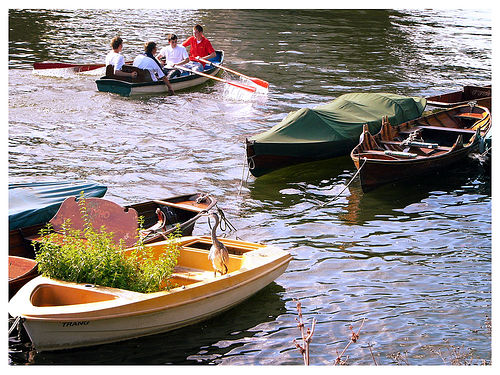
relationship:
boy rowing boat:
[177, 24, 217, 76] [90, 26, 243, 101]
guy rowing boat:
[157, 29, 195, 75] [90, 26, 243, 101]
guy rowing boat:
[131, 41, 177, 96] [90, 26, 243, 101]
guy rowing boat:
[100, 32, 139, 82] [90, 26, 243, 101]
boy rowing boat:
[177, 24, 217, 76] [96, 22, 246, 122]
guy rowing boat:
[153, 32, 190, 75] [96, 22, 246, 122]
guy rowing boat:
[127, 41, 169, 81] [96, 22, 246, 122]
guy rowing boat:
[106, 36, 139, 79] [96, 22, 246, 122]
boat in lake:
[244, 84, 497, 178] [6, 6, 490, 366]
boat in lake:
[247, 79, 432, 179] [6, 6, 490, 366]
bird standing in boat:
[191, 196, 269, 258] [44, 227, 332, 309]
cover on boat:
[248, 92, 427, 157] [350, 100, 493, 193]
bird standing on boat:
[201, 211, 230, 277] [6, 228, 307, 355]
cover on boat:
[241, 89, 427, 144] [248, 92, 428, 177]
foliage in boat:
[34, 217, 176, 292] [12, 235, 291, 350]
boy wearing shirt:
[177, 24, 217, 76] [187, 36, 203, 54]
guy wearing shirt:
[153, 32, 190, 75] [157, 44, 182, 71]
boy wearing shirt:
[177, 24, 217, 76] [174, 34, 216, 68]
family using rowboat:
[103, 21, 224, 72] [94, 46, 228, 97]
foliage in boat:
[31, 189, 187, 294] [6, 228, 307, 355]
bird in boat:
[201, 211, 230, 277] [8, 212, 323, 362]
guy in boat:
[106, 36, 139, 79] [76, 20, 253, 113]